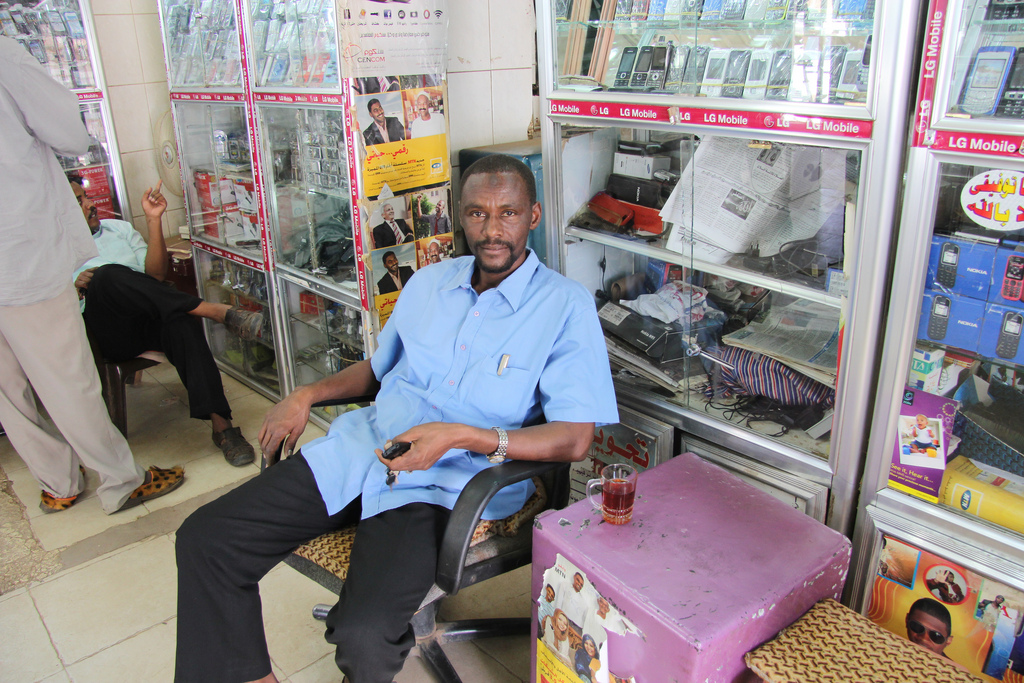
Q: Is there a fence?
A: No, there are no fences.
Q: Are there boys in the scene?
A: No, there are no boys.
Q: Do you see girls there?
A: No, there are no girls.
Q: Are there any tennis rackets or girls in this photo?
A: No, there are no girls or tennis rackets.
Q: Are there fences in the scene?
A: No, there are no fences.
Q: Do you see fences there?
A: No, there are no fences.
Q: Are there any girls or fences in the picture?
A: No, there are no fences or girls.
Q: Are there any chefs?
A: No, there are no chefs.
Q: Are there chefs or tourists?
A: No, there are no chefs or tourists.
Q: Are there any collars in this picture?
A: Yes, there is a collar.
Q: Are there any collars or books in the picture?
A: Yes, there is a collar.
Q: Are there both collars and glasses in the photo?
A: Yes, there are both a collar and glasses.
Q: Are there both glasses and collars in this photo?
A: Yes, there are both a collar and glasses.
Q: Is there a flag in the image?
A: No, there are no flags.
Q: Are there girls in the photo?
A: No, there are no girls.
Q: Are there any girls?
A: No, there are no girls.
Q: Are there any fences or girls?
A: No, there are no girls or fences.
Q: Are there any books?
A: No, there are no books.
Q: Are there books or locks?
A: No, there are no books or locks.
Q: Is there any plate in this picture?
A: No, there are no plates.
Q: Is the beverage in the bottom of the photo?
A: Yes, the beverage is in the bottom of the image.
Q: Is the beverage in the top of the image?
A: No, the beverage is in the bottom of the image.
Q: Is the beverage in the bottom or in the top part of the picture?
A: The beverage is in the bottom of the image.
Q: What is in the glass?
A: The beverage is in the glass.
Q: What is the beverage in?
A: The beverage is in the glass.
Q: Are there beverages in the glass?
A: Yes, there is a beverage in the glass.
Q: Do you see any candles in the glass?
A: No, there is a beverage in the glass.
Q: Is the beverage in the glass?
A: Yes, the beverage is in the glass.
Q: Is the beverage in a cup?
A: No, the beverage is in the glass.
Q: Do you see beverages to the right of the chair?
A: Yes, there is a beverage to the right of the chair.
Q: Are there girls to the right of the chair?
A: No, there is a beverage to the right of the chair.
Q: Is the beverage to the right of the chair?
A: Yes, the beverage is to the right of the chair.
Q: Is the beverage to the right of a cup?
A: No, the beverage is to the right of the chair.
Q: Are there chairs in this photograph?
A: Yes, there is a chair.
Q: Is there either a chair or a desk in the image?
A: Yes, there is a chair.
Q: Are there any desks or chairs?
A: Yes, there is a chair.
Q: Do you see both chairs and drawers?
A: No, there is a chair but no drawers.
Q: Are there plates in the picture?
A: No, there are no plates.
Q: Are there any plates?
A: No, there are no plates.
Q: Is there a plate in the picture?
A: No, there are no plates.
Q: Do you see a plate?
A: No, there are no plates.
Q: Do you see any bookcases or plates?
A: No, there are no plates or bookcases.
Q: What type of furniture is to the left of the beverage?
A: The piece of furniture is a chair.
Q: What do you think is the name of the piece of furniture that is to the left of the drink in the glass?
A: The piece of furniture is a chair.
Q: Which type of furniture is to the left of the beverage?
A: The piece of furniture is a chair.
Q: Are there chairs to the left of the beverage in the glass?
A: Yes, there is a chair to the left of the beverage.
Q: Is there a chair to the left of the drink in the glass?
A: Yes, there is a chair to the left of the beverage.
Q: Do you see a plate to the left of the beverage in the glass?
A: No, there is a chair to the left of the beverage.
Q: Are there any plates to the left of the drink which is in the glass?
A: No, there is a chair to the left of the beverage.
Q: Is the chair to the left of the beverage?
A: Yes, the chair is to the left of the beverage.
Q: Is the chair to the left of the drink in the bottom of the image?
A: Yes, the chair is to the left of the beverage.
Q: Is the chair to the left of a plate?
A: No, the chair is to the left of the beverage.